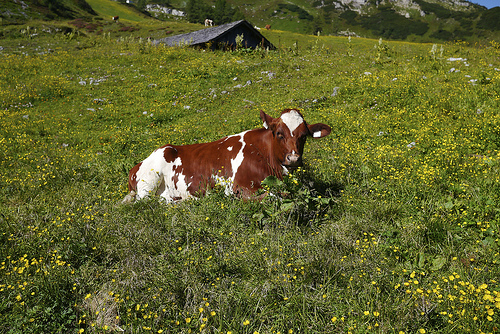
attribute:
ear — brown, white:
[311, 122, 333, 138]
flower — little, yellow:
[361, 307, 371, 317]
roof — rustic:
[148, 18, 280, 51]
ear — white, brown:
[257, 111, 273, 127]